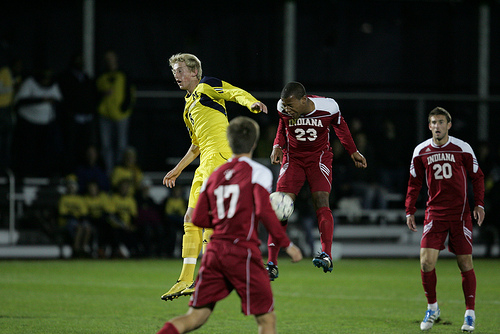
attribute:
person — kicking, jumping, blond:
[160, 55, 271, 302]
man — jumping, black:
[262, 78, 371, 283]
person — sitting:
[56, 173, 97, 258]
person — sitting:
[83, 182, 116, 259]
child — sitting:
[105, 181, 149, 264]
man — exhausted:
[396, 107, 488, 322]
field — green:
[4, 233, 500, 329]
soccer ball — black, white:
[270, 189, 298, 225]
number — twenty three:
[294, 126, 319, 146]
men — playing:
[185, 79, 488, 333]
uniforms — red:
[189, 101, 486, 315]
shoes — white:
[418, 306, 481, 332]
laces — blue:
[422, 309, 475, 324]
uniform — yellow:
[174, 80, 252, 210]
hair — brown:
[425, 109, 456, 123]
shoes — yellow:
[157, 275, 204, 300]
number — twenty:
[426, 157, 452, 183]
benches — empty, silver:
[303, 202, 491, 260]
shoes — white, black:
[263, 250, 334, 289]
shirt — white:
[22, 81, 58, 124]